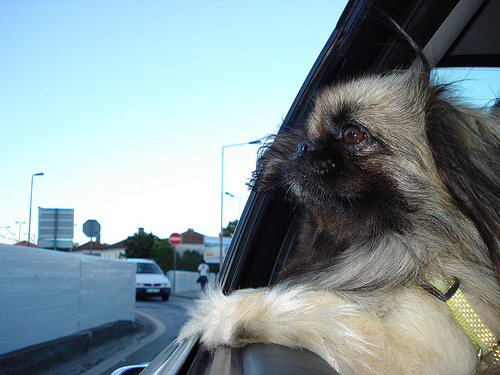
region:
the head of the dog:
[260, 78, 437, 235]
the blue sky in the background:
[30, 19, 197, 84]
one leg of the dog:
[205, 288, 372, 360]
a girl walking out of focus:
[196, 259, 208, 294]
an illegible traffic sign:
[168, 231, 181, 297]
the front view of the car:
[134, 263, 169, 299]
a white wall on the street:
[4, 253, 132, 330]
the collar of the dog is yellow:
[421, 253, 498, 357]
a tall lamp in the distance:
[27, 170, 41, 242]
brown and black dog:
[255, 58, 450, 370]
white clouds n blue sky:
[27, 30, 52, 70]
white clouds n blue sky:
[202, 50, 244, 86]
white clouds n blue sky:
[170, 48, 208, 99]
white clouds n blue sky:
[159, 26, 226, 78]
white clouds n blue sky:
[107, 120, 160, 160]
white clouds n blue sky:
[76, 53, 155, 121]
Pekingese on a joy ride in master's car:
[171, 54, 498, 373]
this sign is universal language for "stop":
[165, 228, 184, 248]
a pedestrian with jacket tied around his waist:
[193, 256, 214, 293]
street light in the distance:
[22, 168, 47, 247]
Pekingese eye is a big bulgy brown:
[322, 112, 387, 158]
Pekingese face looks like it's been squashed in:
[275, 73, 415, 220]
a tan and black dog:
[178, 30, 493, 356]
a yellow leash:
[416, 262, 496, 367]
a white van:
[123, 255, 173, 302]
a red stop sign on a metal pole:
[168, 232, 180, 288]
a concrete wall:
[0, 240, 136, 372]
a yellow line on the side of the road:
[76, 305, 163, 372]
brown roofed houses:
[15, 224, 222, 266]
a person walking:
[193, 258, 210, 288]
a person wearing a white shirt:
[196, 260, 211, 295]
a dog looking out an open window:
[181, 1, 497, 373]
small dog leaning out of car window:
[182, 63, 497, 369]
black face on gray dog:
[273, 32, 490, 240]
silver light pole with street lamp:
[217, 130, 270, 262]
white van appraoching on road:
[129, 253, 171, 309]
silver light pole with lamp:
[23, 168, 53, 240]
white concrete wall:
[4, 242, 139, 357]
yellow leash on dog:
[413, 275, 498, 368]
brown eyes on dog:
[330, 119, 370, 144]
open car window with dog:
[131, 9, 498, 371]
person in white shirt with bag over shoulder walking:
[192, 252, 214, 299]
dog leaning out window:
[183, 59, 498, 374]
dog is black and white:
[177, 47, 499, 374]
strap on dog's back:
[405, 258, 499, 373]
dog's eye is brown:
[335, 114, 367, 146]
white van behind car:
[113, 251, 175, 299]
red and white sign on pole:
[166, 229, 180, 251]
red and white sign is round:
[168, 228, 180, 244]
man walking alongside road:
[192, 256, 209, 298]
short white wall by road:
[1, 239, 142, 364]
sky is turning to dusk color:
[2, 2, 498, 261]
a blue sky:
[7, 29, 284, 276]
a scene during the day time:
[3, 23, 493, 370]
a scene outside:
[7, 21, 490, 373]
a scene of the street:
[10, 18, 497, 361]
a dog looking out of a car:
[178, 20, 496, 372]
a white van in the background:
[112, 242, 186, 312]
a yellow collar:
[392, 253, 499, 373]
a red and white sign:
[163, 225, 200, 320]